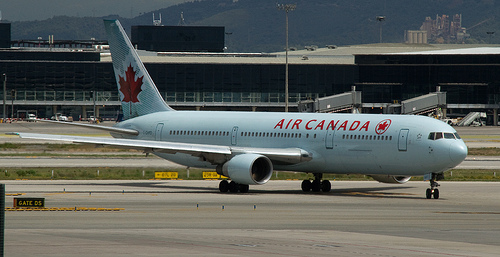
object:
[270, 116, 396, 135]
logo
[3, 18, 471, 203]
airplane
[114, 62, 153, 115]
leaf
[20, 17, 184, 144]
tail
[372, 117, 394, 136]
circle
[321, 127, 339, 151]
door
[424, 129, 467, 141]
windows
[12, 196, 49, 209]
black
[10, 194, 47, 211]
sign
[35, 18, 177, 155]
terminal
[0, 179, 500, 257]
runway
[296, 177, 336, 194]
wheels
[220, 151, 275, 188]
engine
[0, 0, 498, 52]
mountains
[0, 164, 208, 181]
grass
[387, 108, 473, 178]
front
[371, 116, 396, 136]
cirl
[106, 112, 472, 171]
side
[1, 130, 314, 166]
wing